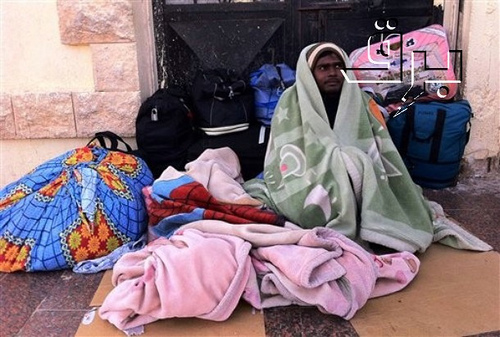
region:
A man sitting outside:
[265, 41, 435, 258]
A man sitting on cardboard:
[275, 43, 481, 328]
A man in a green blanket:
[263, 21, 480, 241]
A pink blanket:
[118, 212, 442, 329]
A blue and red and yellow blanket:
[0, 130, 143, 281]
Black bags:
[116, 56, 266, 216]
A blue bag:
[371, 90, 489, 200]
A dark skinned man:
[289, 40, 378, 182]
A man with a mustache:
[283, 13, 402, 193]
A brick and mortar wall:
[0, 2, 141, 149]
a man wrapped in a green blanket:
[263, 42, 433, 252]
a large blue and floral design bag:
[1, 131, 155, 271]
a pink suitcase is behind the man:
[349, 24, 458, 97]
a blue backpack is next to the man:
[406, 98, 473, 190]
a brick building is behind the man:
[0, 0, 139, 144]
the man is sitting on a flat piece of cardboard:
[344, 247, 497, 334]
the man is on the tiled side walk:
[1, 272, 102, 335]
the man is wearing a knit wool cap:
[306, 41, 348, 69]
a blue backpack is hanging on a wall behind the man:
[249, 45, 296, 125]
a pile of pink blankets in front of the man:
[99, 218, 419, 328]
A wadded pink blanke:
[97, 210, 413, 319]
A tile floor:
[456, 194, 495, 335]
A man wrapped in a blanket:
[266, 39, 430, 242]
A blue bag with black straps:
[374, 98, 475, 181]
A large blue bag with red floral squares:
[2, 125, 154, 274]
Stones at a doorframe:
[58, 7, 134, 97]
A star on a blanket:
[271, 103, 293, 125]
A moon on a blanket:
[299, 181, 342, 222]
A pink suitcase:
[341, 10, 463, 111]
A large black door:
[154, 5, 343, 111]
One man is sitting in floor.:
[282, 55, 368, 220]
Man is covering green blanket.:
[275, 90, 400, 215]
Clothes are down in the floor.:
[40, 141, 325, 286]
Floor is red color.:
[5, 280, 60, 331]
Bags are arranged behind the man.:
[180, 52, 455, 142]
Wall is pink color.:
[7, 21, 128, 116]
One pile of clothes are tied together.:
[11, 157, 146, 262]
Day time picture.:
[22, 45, 487, 300]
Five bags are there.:
[168, 62, 483, 166]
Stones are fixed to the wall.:
[10, 8, 165, 135]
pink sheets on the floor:
[99, 223, 427, 335]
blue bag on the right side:
[384, 96, 469, 188]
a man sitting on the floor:
[267, 40, 393, 222]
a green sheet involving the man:
[261, 40, 444, 228]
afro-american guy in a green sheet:
[287, 36, 369, 238]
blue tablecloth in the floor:
[1, 139, 153, 279]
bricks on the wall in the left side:
[0, 0, 170, 151]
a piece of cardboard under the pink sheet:
[79, 245, 271, 332]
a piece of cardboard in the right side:
[321, 243, 496, 335]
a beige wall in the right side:
[427, 0, 496, 165]